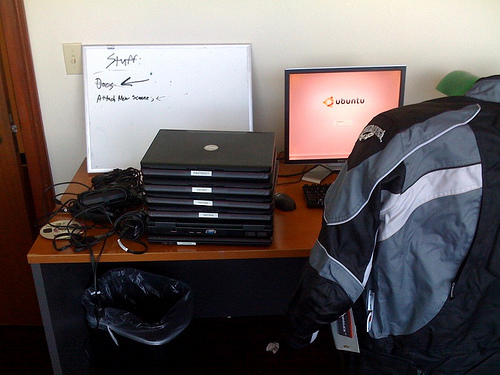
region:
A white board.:
[71, 38, 266, 196]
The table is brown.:
[283, 221, 313, 251]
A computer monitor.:
[273, 59, 411, 182]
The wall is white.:
[268, 5, 423, 45]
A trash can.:
[66, 260, 203, 367]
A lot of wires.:
[45, 160, 161, 270]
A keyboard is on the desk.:
[290, 176, 385, 216]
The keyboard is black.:
[295, 170, 370, 215]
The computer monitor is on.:
[275, 55, 415, 180]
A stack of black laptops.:
[135, 122, 282, 267]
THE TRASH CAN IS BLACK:
[79, 261, 201, 373]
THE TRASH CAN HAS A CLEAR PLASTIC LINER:
[79, 256, 201, 361]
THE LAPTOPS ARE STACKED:
[135, 120, 289, 252]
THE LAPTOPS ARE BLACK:
[133, 111, 279, 258]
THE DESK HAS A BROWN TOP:
[23, 151, 368, 373]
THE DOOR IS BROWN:
[0, 0, 73, 335]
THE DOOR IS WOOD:
[0, 1, 57, 339]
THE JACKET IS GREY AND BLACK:
[267, 75, 499, 370]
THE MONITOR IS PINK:
[282, 65, 405, 172]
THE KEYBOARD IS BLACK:
[301, 180, 339, 216]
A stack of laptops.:
[147, 127, 280, 242]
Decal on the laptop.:
[194, 139, 223, 153]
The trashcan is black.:
[86, 338, 160, 374]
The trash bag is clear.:
[113, 297, 164, 330]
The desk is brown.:
[268, 217, 315, 256]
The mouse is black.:
[259, 194, 314, 220]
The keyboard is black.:
[292, 180, 343, 231]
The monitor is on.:
[298, 120, 355, 151]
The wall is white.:
[280, 10, 355, 52]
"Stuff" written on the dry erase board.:
[104, 48, 157, 79]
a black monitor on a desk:
[282, 65, 405, 156]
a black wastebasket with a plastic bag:
[91, 271, 194, 351]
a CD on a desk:
[37, 211, 82, 241]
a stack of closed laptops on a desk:
[138, 127, 279, 252]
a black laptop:
[137, 123, 273, 178]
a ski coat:
[288, 81, 498, 367]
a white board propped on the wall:
[80, 38, 260, 144]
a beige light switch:
[56, 36, 82, 78]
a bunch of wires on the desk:
[65, 170, 143, 243]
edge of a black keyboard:
[296, 175, 336, 214]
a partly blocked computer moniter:
[278, 63, 405, 158]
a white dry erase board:
[81, 42, 251, 169]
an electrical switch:
[58, 41, 86, 83]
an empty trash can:
[90, 266, 187, 372]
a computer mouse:
[275, 185, 296, 221]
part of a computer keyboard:
[300, 179, 336, 210]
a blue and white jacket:
[293, 87, 497, 355]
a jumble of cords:
[31, 162, 145, 264]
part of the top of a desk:
[29, 150, 354, 299]